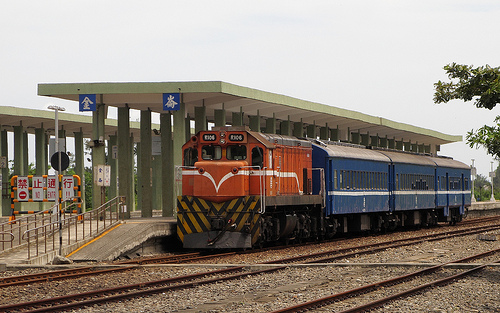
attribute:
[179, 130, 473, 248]
train — red blue white yello, red, blue, black, yellow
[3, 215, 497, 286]
track — brown, pictured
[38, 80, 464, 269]
station — pictured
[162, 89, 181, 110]
sign — blue, white, train identification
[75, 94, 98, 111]
sign — blue, white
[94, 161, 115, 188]
sign — white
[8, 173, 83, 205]
sign — red, white, warning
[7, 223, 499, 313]
track — brown, pictured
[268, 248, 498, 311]
track — brown, pictured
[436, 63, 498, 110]
branch — green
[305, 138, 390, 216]
car — blue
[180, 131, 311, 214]
engine — orange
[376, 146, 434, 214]
car — blue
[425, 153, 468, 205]
car — blue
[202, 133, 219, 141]
sign — train id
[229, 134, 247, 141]
sign — train id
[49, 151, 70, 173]
traffic sign — backwards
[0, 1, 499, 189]
sky — clear, cloudy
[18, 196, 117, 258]
railing — metal, silver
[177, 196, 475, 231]
bottom — black, yellow